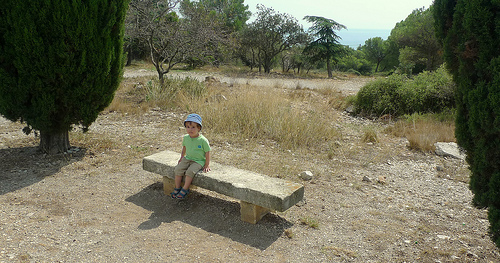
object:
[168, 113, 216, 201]
person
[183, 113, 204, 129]
hat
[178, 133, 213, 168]
shirt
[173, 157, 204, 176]
short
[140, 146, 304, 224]
park bench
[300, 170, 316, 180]
rock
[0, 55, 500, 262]
ground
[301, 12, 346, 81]
tree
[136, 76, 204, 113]
shrub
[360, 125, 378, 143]
weeds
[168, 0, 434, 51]
sky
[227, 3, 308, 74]
tree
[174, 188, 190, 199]
sandal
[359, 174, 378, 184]
gravel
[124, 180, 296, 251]
shadow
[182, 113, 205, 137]
head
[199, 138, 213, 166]
arm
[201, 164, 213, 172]
hand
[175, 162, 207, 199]
leg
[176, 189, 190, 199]
foot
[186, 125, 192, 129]
eye